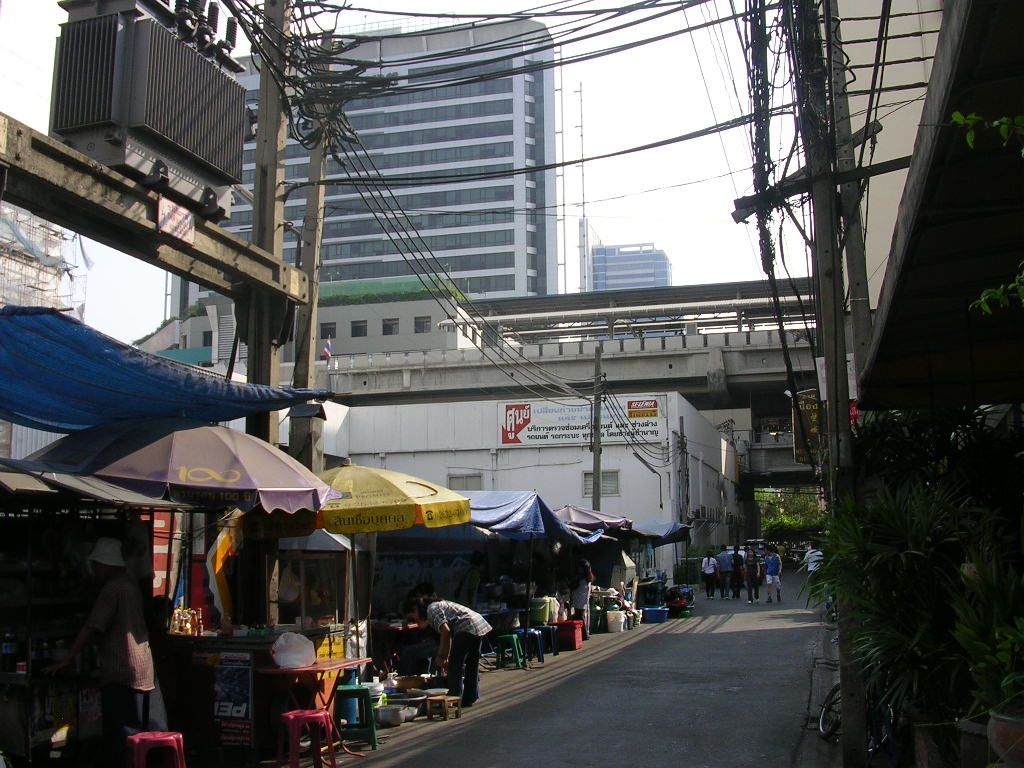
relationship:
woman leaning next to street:
[390, 575, 512, 690] [312, 619, 613, 764]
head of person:
[405, 588, 432, 630] [402, 592, 495, 708]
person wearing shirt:
[402, 592, 495, 708] [420, 599, 503, 645]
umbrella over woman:
[291, 450, 469, 539] [373, 549, 520, 712]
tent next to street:
[440, 482, 583, 565] [578, 657, 738, 757]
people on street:
[723, 519, 778, 597] [695, 603, 782, 677]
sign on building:
[511, 405, 686, 451] [388, 310, 717, 643]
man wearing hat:
[57, 521, 183, 712] [46, 517, 153, 593]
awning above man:
[25, 457, 134, 524] [44, 511, 239, 734]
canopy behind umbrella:
[344, 431, 448, 527] [455, 471, 570, 562]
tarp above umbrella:
[59, 294, 224, 415] [111, 418, 248, 499]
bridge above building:
[327, 331, 749, 399] [375, 353, 654, 513]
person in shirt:
[425, 584, 510, 708] [403, 567, 490, 643]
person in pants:
[425, 584, 510, 708] [438, 631, 534, 731]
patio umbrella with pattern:
[18, 381, 360, 531] [152, 450, 254, 494]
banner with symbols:
[484, 387, 688, 465] [493, 398, 533, 450]